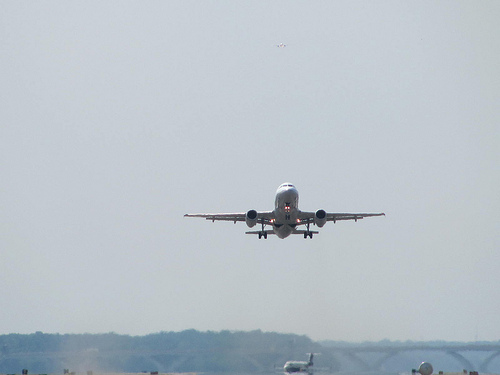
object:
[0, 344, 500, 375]
bridge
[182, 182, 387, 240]
airplane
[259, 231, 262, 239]
wheels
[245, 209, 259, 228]
engines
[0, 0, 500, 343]
sky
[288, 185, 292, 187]
windows